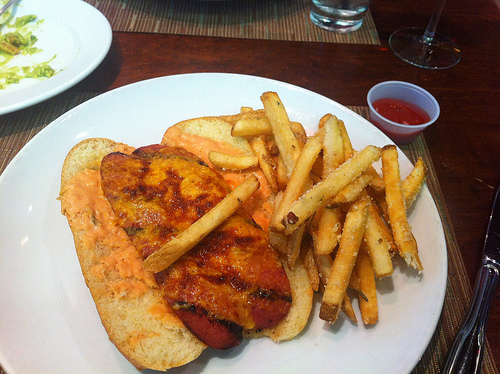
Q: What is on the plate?
A: A hot dog and french fries.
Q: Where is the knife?
A: To the right of the plate.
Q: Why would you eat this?
A: Because you are hungry.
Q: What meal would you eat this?
A: Lunch or Dinner.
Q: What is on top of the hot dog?
A: A french fry.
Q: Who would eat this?
A: People that like hot dogs.